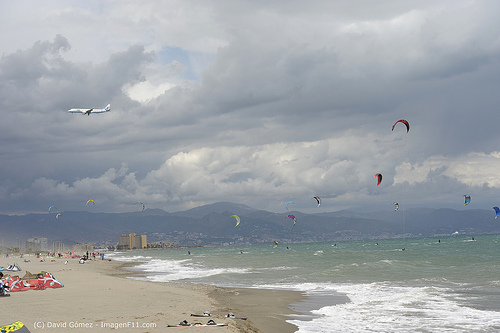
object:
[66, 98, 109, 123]
plane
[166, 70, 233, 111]
sky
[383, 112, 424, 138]
kite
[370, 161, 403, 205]
kite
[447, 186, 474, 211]
kite